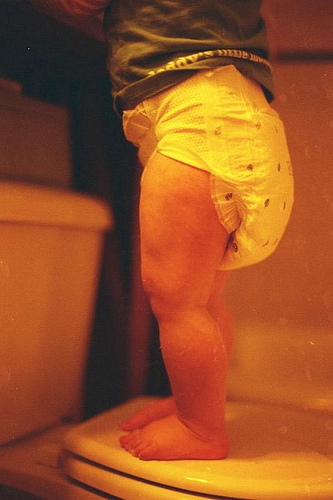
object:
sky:
[298, 92, 311, 106]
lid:
[61, 392, 332, 499]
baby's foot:
[119, 412, 230, 460]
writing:
[147, 49, 272, 78]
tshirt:
[104, 0, 275, 115]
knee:
[140, 271, 210, 340]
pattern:
[253, 117, 264, 136]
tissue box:
[2, 79, 75, 191]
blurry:
[1, 77, 72, 189]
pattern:
[263, 199, 271, 208]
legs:
[138, 204, 231, 428]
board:
[75, 399, 333, 500]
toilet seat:
[64, 393, 333, 497]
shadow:
[216, 383, 332, 460]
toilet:
[0, 0, 333, 500]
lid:
[0, 179, 112, 229]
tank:
[0, 182, 108, 438]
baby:
[52, 3, 296, 458]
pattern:
[273, 153, 287, 180]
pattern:
[262, 240, 270, 247]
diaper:
[120, 60, 298, 273]